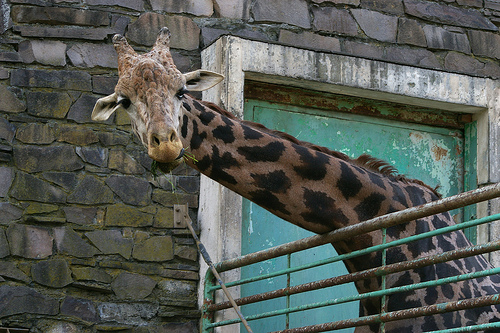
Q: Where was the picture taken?
A: A zoo.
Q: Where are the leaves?
A: In giraffes mouth.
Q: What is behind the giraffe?
A: A door.